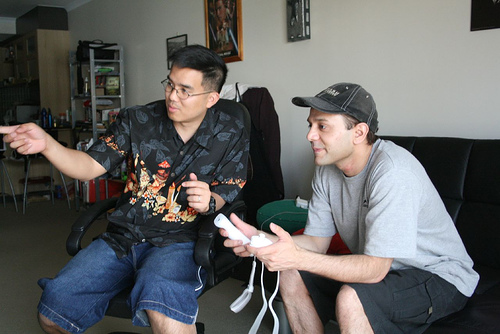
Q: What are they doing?
A: Watching.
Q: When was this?
A: Daytime.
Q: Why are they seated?
A: To relax.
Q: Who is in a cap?
A: One on the right.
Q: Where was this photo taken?
A: In a living room.